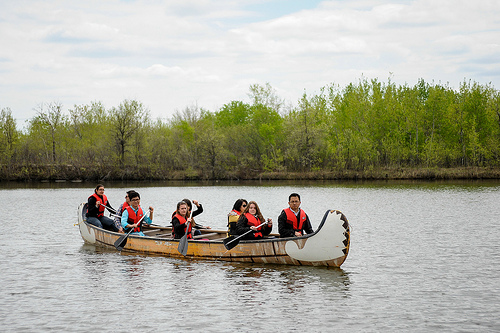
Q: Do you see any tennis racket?
A: No, there are no rackets.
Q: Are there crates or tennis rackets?
A: No, there are no tennis rackets or crates.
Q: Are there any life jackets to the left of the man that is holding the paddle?
A: Yes, there is a life jacket to the left of the man.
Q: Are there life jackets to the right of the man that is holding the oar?
A: No, the life jacket is to the left of the man.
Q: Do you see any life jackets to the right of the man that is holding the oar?
A: No, the life jacket is to the left of the man.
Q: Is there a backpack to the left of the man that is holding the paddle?
A: No, there is a life jacket to the left of the man.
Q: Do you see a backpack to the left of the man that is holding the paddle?
A: No, there is a life jacket to the left of the man.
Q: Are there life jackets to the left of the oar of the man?
A: Yes, there is a life jacket to the left of the oar.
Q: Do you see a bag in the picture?
A: No, there are no bags.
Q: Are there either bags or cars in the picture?
A: No, there are no bags or cars.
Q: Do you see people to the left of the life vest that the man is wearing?
A: Yes, there is a person to the left of the life vest.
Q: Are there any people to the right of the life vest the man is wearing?
A: No, the person is to the left of the life jacket.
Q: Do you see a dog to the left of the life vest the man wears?
A: No, there is a person to the left of the life jacket.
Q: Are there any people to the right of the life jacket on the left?
A: Yes, there is a person to the right of the life vest.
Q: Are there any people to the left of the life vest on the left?
A: No, the person is to the right of the life jacket.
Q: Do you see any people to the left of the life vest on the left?
A: No, the person is to the right of the life jacket.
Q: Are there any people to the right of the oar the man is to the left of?
A: Yes, there is a person to the right of the paddle.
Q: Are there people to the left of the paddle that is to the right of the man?
A: No, the person is to the right of the paddle.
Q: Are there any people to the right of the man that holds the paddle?
A: Yes, there is a person to the right of the man.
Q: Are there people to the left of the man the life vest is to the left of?
A: No, the person is to the right of the man.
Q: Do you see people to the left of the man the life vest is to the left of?
A: No, the person is to the right of the man.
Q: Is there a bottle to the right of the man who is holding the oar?
A: No, there is a person to the right of the man.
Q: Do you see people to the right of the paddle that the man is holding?
A: Yes, there is a person to the right of the oar.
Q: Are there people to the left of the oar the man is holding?
A: No, the person is to the right of the oar.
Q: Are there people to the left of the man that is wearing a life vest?
A: Yes, there is a person to the left of the man.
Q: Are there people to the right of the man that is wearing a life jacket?
A: No, the person is to the left of the man.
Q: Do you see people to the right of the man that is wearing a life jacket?
A: No, the person is to the left of the man.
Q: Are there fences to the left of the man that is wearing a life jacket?
A: No, there is a person to the left of the man.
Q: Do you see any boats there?
A: Yes, there is a boat.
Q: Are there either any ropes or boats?
A: Yes, there is a boat.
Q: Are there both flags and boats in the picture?
A: No, there is a boat but no flags.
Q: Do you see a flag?
A: No, there are no flags.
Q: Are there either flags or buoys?
A: No, there are no flags or buoys.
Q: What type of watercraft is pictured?
A: The watercraft is a boat.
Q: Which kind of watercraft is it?
A: The watercraft is a boat.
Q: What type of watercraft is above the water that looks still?
A: The watercraft is a boat.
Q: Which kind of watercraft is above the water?
A: The watercraft is a boat.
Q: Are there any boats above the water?
A: Yes, there is a boat above the water.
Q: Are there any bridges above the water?
A: No, there is a boat above the water.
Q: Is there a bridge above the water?
A: No, there is a boat above the water.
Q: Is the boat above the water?
A: Yes, the boat is above the water.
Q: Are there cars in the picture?
A: No, there are no cars.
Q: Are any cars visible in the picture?
A: No, there are no cars.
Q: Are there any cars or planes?
A: No, there are no cars or planes.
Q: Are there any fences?
A: No, there are no fences.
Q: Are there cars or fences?
A: No, there are no fences or cars.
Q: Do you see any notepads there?
A: No, there are no notepads.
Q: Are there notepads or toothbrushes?
A: No, there are no notepads or toothbrushes.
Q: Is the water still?
A: Yes, the water is still.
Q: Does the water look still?
A: Yes, the water is still.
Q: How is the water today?
A: The water is still.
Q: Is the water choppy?
A: No, the water is still.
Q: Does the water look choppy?
A: No, the water is still.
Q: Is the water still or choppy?
A: The water is still.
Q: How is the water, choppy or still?
A: The water is still.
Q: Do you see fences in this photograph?
A: No, there are no fences.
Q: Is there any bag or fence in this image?
A: No, there are no fences or bags.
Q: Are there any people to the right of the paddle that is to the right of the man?
A: Yes, there are people to the right of the paddle.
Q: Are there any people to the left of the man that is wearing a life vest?
A: Yes, there are people to the left of the man.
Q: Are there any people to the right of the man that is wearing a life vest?
A: No, the people are to the left of the man.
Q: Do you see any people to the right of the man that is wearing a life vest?
A: No, the people are to the left of the man.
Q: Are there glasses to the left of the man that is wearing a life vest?
A: No, there are people to the left of the man.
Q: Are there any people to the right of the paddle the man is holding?
A: Yes, there are people to the right of the paddle.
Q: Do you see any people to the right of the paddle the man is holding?
A: Yes, there are people to the right of the paddle.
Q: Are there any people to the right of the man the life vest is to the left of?
A: Yes, there are people to the right of the man.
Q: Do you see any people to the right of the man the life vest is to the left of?
A: Yes, there are people to the right of the man.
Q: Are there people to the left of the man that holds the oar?
A: No, the people are to the right of the man.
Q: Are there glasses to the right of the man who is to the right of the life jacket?
A: No, there are people to the right of the man.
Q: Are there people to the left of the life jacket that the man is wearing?
A: Yes, there are people to the left of the life jacket.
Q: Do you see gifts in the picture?
A: No, there are no gifts.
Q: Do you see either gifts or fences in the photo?
A: No, there are no gifts or fences.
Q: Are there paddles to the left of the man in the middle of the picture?
A: Yes, there is a paddle to the left of the man.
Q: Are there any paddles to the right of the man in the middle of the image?
A: No, the paddle is to the left of the man.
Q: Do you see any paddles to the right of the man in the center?
A: No, the paddle is to the left of the man.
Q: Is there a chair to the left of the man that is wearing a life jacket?
A: No, there is a paddle to the left of the man.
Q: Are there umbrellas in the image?
A: No, there are no umbrellas.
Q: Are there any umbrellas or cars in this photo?
A: No, there are no umbrellas or cars.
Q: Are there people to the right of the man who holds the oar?
A: Yes, there are people to the right of the man.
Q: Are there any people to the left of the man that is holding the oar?
A: No, the people are to the right of the man.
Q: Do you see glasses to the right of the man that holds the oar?
A: No, there are people to the right of the man.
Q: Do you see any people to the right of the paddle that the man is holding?
A: Yes, there are people to the right of the paddle.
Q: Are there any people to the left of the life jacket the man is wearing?
A: Yes, there are people to the left of the life jacket.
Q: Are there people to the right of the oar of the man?
A: Yes, there are people to the right of the paddle.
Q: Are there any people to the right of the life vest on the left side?
A: Yes, there are people to the right of the life jacket.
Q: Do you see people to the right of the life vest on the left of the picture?
A: Yes, there are people to the right of the life jacket.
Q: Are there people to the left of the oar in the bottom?
A: Yes, there are people to the left of the oar.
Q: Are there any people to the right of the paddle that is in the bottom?
A: No, the people are to the left of the oar.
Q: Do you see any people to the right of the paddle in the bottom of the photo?
A: No, the people are to the left of the oar.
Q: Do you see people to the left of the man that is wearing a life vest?
A: Yes, there are people to the left of the man.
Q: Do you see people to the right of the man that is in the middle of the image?
A: No, the people are to the left of the man.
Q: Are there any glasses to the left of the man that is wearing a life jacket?
A: No, there are people to the left of the man.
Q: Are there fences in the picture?
A: No, there are no fences.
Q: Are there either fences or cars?
A: No, there are no fences or cars.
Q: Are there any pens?
A: No, there are no pens.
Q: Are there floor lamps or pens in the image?
A: No, there are no pens or floor lamps.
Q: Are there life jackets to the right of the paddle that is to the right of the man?
A: Yes, there is a life jacket to the right of the oar.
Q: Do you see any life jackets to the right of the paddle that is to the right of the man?
A: Yes, there is a life jacket to the right of the oar.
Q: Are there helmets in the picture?
A: No, there are no helmets.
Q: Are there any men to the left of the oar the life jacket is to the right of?
A: Yes, there is a man to the left of the paddle.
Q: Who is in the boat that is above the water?
A: The man is in the boat.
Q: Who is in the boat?
A: The man is in the boat.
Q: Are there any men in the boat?
A: Yes, there is a man in the boat.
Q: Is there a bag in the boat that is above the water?
A: No, there is a man in the boat.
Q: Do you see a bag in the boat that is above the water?
A: No, there is a man in the boat.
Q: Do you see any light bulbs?
A: No, there are no light bulbs.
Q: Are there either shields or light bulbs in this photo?
A: No, there are no light bulbs or shields.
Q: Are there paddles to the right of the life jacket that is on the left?
A: Yes, there is a paddle to the right of the life vest.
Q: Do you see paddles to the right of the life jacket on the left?
A: Yes, there is a paddle to the right of the life vest.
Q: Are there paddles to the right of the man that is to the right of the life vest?
A: Yes, there is a paddle to the right of the man.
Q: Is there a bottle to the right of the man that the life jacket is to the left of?
A: No, there is a paddle to the right of the man.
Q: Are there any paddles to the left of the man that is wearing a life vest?
A: Yes, there is a paddle to the left of the man.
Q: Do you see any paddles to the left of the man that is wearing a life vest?
A: Yes, there is a paddle to the left of the man.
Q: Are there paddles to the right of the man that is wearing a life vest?
A: No, the paddle is to the left of the man.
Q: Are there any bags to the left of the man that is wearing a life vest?
A: No, there is a paddle to the left of the man.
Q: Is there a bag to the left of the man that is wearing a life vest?
A: No, there is a paddle to the left of the man.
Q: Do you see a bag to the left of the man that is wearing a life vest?
A: No, there is a paddle to the left of the man.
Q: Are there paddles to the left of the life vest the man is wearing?
A: Yes, there is a paddle to the left of the life jacket.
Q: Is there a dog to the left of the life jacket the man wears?
A: No, there is a paddle to the left of the life vest.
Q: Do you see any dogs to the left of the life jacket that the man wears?
A: No, there is a paddle to the left of the life vest.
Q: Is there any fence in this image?
A: No, there are no fences.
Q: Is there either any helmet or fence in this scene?
A: No, there are no fences or helmets.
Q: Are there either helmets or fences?
A: No, there are no fences or helmets.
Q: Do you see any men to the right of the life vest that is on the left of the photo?
A: Yes, there is a man to the right of the life vest.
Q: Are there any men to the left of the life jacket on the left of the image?
A: No, the man is to the right of the life vest.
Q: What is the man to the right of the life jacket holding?
A: The man is holding the paddle.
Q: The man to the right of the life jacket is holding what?
A: The man is holding the paddle.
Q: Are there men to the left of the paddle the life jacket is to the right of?
A: Yes, there is a man to the left of the paddle.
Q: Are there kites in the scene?
A: No, there are no kites.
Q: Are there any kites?
A: No, there are no kites.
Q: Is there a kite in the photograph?
A: No, there are no kites.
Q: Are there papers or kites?
A: No, there are no kites or papers.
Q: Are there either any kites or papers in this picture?
A: No, there are no kites or papers.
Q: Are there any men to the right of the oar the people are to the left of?
A: Yes, there is a man to the right of the paddle.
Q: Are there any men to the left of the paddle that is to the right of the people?
A: No, the man is to the right of the oar.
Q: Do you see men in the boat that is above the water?
A: Yes, there is a man in the boat.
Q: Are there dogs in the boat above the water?
A: No, there is a man in the boat.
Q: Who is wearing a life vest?
A: The man is wearing a life vest.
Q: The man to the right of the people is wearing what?
A: The man is wearing a life vest.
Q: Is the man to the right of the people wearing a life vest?
A: Yes, the man is wearing a life vest.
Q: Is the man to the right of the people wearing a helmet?
A: No, the man is wearing a life vest.